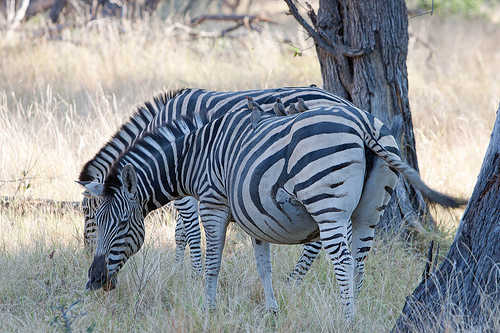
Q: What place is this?
A: It is a field.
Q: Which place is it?
A: It is a field.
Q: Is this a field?
A: Yes, it is a field.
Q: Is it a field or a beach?
A: It is a field.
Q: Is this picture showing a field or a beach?
A: It is showing a field.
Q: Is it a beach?
A: No, it is a field.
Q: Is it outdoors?
A: Yes, it is outdoors.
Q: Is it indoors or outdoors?
A: It is outdoors.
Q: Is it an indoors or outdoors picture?
A: It is outdoors.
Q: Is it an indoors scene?
A: No, it is outdoors.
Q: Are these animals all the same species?
A: No, there are both zebras and birds.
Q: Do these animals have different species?
A: Yes, they are zebras and birds.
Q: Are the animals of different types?
A: Yes, they are zebras and birds.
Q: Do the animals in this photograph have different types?
A: Yes, they are zebras and birds.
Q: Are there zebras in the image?
A: Yes, there are zebras.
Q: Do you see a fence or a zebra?
A: Yes, there are zebras.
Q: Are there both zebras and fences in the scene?
A: No, there are zebras but no fences.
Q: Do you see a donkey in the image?
A: No, there are no donkeys.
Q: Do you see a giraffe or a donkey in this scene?
A: No, there are no donkeys or giraffes.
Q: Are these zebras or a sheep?
A: These are zebras.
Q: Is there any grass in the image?
A: Yes, there is grass.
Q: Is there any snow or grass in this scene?
A: Yes, there is grass.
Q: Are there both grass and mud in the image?
A: No, there is grass but no mud.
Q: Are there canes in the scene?
A: No, there are no canes.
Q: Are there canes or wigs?
A: No, there are no canes or wigs.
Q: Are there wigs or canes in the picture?
A: No, there are no canes or wigs.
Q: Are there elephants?
A: No, there are no elephants.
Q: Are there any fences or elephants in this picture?
A: No, there are no elephants or fences.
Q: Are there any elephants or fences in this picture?
A: No, there are no elephants or fences.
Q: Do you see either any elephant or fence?
A: No, there are no elephants or fences.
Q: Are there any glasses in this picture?
A: No, there are no glasses.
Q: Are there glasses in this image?
A: No, there are no glasses.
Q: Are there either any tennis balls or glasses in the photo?
A: No, there are no glasses or tennis balls.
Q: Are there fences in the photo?
A: No, there are no fences.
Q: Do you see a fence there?
A: No, there are no fences.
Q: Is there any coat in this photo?
A: Yes, there is a coat.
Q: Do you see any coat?
A: Yes, there is a coat.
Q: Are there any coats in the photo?
A: Yes, there is a coat.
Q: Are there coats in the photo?
A: Yes, there is a coat.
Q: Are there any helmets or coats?
A: Yes, there is a coat.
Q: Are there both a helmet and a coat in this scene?
A: No, there is a coat but no helmets.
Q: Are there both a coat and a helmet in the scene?
A: No, there is a coat but no helmets.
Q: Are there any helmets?
A: No, there are no helmets.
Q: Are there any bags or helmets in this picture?
A: No, there are no helmets or bags.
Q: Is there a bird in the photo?
A: Yes, there are birds.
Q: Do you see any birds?
A: Yes, there are birds.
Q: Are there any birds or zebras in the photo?
A: Yes, there are birds.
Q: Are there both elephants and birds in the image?
A: No, there are birds but no elephants.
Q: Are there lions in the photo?
A: No, there are no lions.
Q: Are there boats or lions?
A: No, there are no lions or boats.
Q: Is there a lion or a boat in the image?
A: No, there are no lions or boats.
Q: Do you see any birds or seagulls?
A: Yes, there are birds.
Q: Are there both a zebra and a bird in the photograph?
A: Yes, there are both a bird and a zebra.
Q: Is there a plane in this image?
A: No, there are no airplanes.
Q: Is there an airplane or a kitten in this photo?
A: No, there are no airplanes or kittens.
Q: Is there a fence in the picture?
A: No, there are no fences.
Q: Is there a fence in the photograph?
A: No, there are no fences.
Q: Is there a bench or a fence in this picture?
A: No, there are no fences or benches.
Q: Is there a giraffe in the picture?
A: No, there are no giraffes.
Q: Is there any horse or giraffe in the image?
A: No, there are no giraffes or horses.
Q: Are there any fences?
A: No, there are no fences.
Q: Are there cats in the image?
A: No, there are no cats.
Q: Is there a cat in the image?
A: No, there are no cats.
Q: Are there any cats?
A: No, there are no cats.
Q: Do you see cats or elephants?
A: No, there are no cats or elephants.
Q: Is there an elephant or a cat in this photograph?
A: No, there are no cats or elephants.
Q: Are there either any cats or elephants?
A: No, there are no cats or elephants.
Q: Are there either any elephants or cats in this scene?
A: No, there are no cats or elephants.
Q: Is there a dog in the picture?
A: No, there are no dogs.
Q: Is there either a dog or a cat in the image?
A: No, there are no dogs or cats.